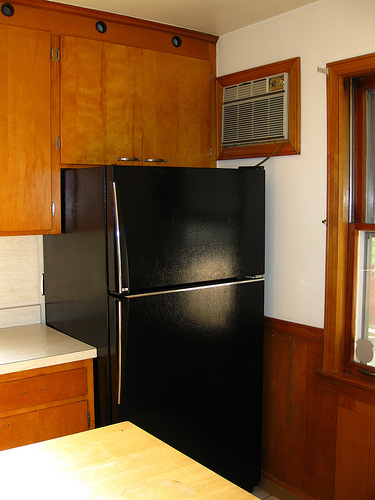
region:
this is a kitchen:
[67, 116, 264, 435]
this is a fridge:
[124, 222, 233, 478]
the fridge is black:
[95, 281, 271, 443]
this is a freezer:
[143, 247, 160, 255]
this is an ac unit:
[212, 89, 341, 123]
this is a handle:
[108, 252, 126, 310]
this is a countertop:
[28, 322, 85, 371]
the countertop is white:
[13, 331, 54, 386]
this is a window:
[306, 310, 368, 340]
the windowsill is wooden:
[310, 295, 363, 367]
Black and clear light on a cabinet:
[166, 29, 187, 48]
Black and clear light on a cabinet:
[89, 15, 112, 36]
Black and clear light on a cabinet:
[1, 1, 18, 17]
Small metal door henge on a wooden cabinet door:
[53, 43, 64, 64]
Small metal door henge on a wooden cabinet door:
[52, 132, 62, 151]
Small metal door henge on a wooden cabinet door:
[45, 198, 61, 224]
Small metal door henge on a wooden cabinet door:
[42, 44, 53, 63]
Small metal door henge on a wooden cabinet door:
[203, 68, 214, 91]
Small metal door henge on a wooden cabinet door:
[206, 139, 212, 160]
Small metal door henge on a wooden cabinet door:
[81, 405, 98, 428]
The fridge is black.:
[43, 164, 266, 491]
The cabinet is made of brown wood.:
[0, 0, 219, 236]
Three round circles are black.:
[1, 3, 182, 47]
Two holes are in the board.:
[0, 367, 88, 411]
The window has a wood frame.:
[325, 52, 374, 393]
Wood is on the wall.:
[264, 317, 373, 499]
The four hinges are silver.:
[49, 43, 61, 218]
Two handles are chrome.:
[116, 155, 171, 161]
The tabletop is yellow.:
[0, 419, 263, 498]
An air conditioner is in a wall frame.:
[215, 56, 302, 151]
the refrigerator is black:
[63, 157, 271, 464]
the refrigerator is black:
[57, 162, 270, 497]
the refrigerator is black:
[87, 150, 312, 417]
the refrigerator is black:
[73, 158, 306, 465]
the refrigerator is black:
[85, 174, 296, 409]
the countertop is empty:
[3, 298, 77, 393]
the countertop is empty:
[6, 303, 98, 382]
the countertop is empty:
[1, 291, 96, 384]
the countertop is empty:
[1, 291, 99, 401]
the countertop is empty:
[1, 291, 96, 396]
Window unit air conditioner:
[222, 71, 287, 142]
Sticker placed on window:
[355, 337, 373, 363]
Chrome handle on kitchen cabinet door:
[118, 157, 140, 161]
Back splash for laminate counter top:
[0, 304, 41, 327]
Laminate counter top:
[0, 323, 96, 373]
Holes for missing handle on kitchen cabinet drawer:
[21, 386, 46, 394]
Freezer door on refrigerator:
[104, 164, 265, 294]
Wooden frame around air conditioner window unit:
[217, 54, 302, 159]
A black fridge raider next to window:
[94, 160, 282, 450]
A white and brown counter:
[19, 321, 94, 443]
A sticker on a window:
[350, 324, 372, 378]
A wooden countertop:
[50, 431, 151, 478]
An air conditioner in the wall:
[197, 61, 315, 163]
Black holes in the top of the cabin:
[25, 13, 206, 30]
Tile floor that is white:
[259, 483, 285, 497]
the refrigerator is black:
[44, 163, 266, 490]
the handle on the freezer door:
[105, 163, 265, 295]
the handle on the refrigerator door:
[109, 275, 265, 492]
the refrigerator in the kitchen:
[0, 0, 373, 498]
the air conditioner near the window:
[219, 53, 374, 384]